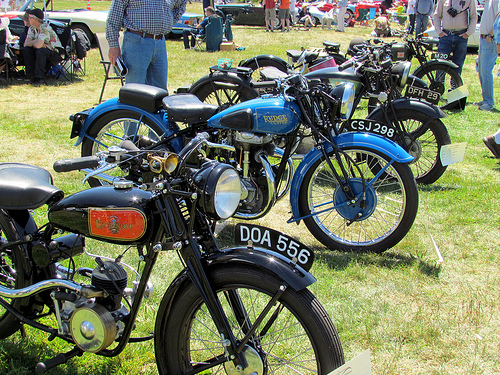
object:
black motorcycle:
[1, 144, 343, 372]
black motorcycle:
[188, 41, 460, 186]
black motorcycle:
[341, 21, 468, 115]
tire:
[164, 263, 342, 373]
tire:
[0, 207, 44, 337]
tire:
[370, 114, 451, 185]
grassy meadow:
[0, 17, 497, 373]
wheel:
[146, 256, 343, 373]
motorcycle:
[114, 73, 424, 253]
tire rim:
[209, 246, 317, 290]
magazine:
[112, 55, 128, 76]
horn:
[81, 137, 188, 181]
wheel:
[298, 147, 415, 257]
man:
[432, 0, 476, 90]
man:
[477, 0, 489, 109]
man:
[415, 1, 432, 33]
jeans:
[121, 34, 168, 139]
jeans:
[480, 35, 490, 111]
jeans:
[435, 30, 467, 86]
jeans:
[414, 12, 428, 35]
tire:
[81, 109, 173, 189]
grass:
[4, 4, 491, 372]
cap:
[26, 9, 46, 20]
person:
[13, 5, 67, 85]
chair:
[33, 15, 79, 84]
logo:
[86, 200, 151, 250]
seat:
[111, 65, 243, 130]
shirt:
[106, 0, 188, 47]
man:
[106, 0, 188, 146]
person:
[94, 0, 179, 98]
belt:
[124, 20, 170, 45]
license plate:
[235, 222, 315, 273]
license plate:
[343, 119, 396, 136]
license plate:
[404, 85, 440, 106]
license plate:
[430, 51, 450, 60]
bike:
[65, 61, 417, 264]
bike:
[175, 39, 455, 194]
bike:
[289, 31, 469, 114]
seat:
[155, 85, 209, 125]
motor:
[204, 105, 303, 132]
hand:
[108, 47, 122, 65]